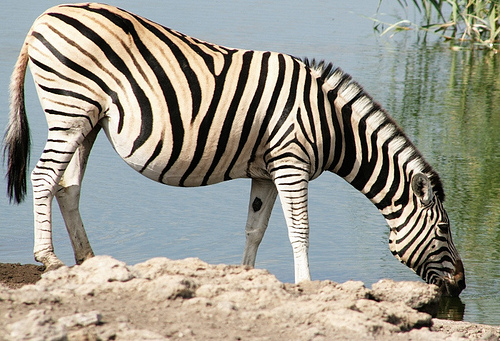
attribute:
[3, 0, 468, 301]
zebra — outdoors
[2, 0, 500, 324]
water — calm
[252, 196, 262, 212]
spot — black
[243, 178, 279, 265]
leg — thin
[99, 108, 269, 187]
belly — huge, plump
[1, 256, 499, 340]
ground — dry, tan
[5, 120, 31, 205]
hair — black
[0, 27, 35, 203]
tail — long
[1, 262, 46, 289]
ground — wet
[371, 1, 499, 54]
plants — green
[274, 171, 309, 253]
stripes — thin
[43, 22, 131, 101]
stripe — brown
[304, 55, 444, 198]
mane — bristly, black, white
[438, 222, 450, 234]
eye — open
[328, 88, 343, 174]
stripe — black